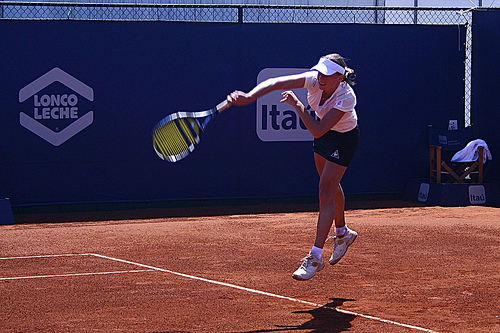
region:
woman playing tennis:
[146, 27, 398, 283]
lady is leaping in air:
[145, 24, 394, 315]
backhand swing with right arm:
[139, 73, 308, 170]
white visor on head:
[310, 53, 351, 77]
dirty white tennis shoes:
[285, 245, 327, 281]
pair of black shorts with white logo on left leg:
[307, 123, 361, 167]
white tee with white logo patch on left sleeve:
[285, 71, 362, 136]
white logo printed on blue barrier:
[11, 60, 96, 151]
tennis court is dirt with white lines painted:
[35, 228, 240, 325]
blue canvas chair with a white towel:
[424, 110, 491, 205]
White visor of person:
[309, 53, 350, 78]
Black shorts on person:
[296, 119, 368, 174]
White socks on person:
[292, 219, 349, 255]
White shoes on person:
[285, 225, 362, 285]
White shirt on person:
[295, 62, 361, 137]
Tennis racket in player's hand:
[130, 83, 240, 175]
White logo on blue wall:
[248, 60, 347, 152]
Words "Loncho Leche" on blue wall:
[31, 90, 81, 126]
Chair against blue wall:
[414, 110, 491, 183]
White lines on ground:
[0, 237, 445, 330]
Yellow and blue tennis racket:
[136, 95, 220, 167]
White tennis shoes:
[271, 215, 397, 278]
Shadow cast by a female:
[273, 290, 374, 332]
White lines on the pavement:
[80, 240, 200, 290]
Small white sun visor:
[290, 49, 367, 81]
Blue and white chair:
[408, 95, 496, 210]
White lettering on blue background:
[6, 34, 106, 149]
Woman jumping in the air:
[135, 30, 379, 292]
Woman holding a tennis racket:
[113, 23, 397, 312]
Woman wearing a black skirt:
[130, 45, 402, 290]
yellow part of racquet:
[147, 124, 219, 183]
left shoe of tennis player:
[291, 250, 347, 290]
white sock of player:
[312, 239, 327, 261]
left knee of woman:
[308, 178, 346, 213]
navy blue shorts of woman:
[293, 113, 370, 176]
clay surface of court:
[164, 218, 299, 286]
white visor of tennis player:
[310, 56, 347, 80]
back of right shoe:
[345, 225, 362, 243]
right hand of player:
[226, 84, 271, 127]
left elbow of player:
[297, 114, 332, 146]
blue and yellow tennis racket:
[148, 94, 242, 166]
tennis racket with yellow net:
[147, 88, 233, 168]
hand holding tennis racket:
[151, 77, 251, 169]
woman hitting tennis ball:
[147, 49, 364, 291]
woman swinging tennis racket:
[144, 56, 379, 284]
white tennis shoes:
[297, 229, 370, 289]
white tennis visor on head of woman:
[307, 50, 367, 96]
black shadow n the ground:
[280, 294, 365, 331]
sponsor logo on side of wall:
[13, 60, 102, 156]